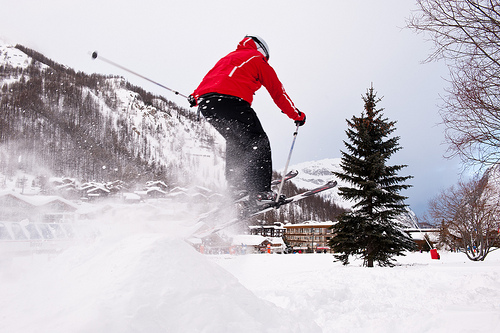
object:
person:
[87, 34, 339, 239]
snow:
[47, 234, 197, 305]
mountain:
[0, 44, 228, 199]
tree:
[420, 177, 498, 261]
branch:
[329, 171, 379, 189]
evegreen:
[326, 81, 420, 267]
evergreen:
[324, 81, 419, 267]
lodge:
[230, 234, 275, 256]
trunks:
[394, 0, 499, 182]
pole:
[87, 50, 189, 99]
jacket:
[190, 37, 305, 121]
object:
[428, 248, 441, 259]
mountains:
[270, 157, 351, 218]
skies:
[277, 0, 405, 57]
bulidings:
[282, 219, 347, 254]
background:
[0, 33, 499, 254]